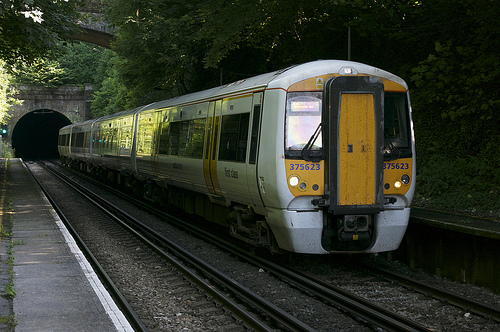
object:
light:
[299, 181, 307, 189]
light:
[401, 174, 410, 184]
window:
[61, 134, 67, 145]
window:
[75, 131, 84, 147]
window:
[218, 112, 251, 163]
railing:
[0, 1, 121, 46]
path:
[4, 158, 128, 332]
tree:
[405, 36, 500, 135]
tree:
[86, 57, 149, 115]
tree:
[112, 0, 205, 97]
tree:
[190, 0, 323, 72]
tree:
[0, 1, 85, 77]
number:
[315, 163, 322, 170]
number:
[404, 163, 409, 169]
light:
[2, 129, 7, 133]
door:
[203, 99, 223, 199]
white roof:
[59, 67, 296, 127]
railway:
[37, 154, 415, 329]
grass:
[0, 145, 15, 236]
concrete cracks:
[1, 157, 12, 329]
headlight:
[289, 176, 301, 186]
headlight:
[394, 181, 403, 188]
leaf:
[79, 42, 82, 45]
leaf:
[74, 44, 75, 45]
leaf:
[54, 86, 57, 88]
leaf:
[34, 57, 37, 60]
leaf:
[28, 49, 32, 53]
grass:
[5, 282, 15, 300]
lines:
[18, 158, 138, 330]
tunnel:
[2, 81, 95, 159]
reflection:
[92, 96, 209, 159]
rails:
[34, 159, 275, 332]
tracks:
[276, 255, 500, 330]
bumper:
[265, 207, 411, 254]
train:
[55, 58, 420, 256]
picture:
[0, 0, 499, 330]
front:
[263, 60, 424, 257]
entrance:
[8, 107, 78, 158]